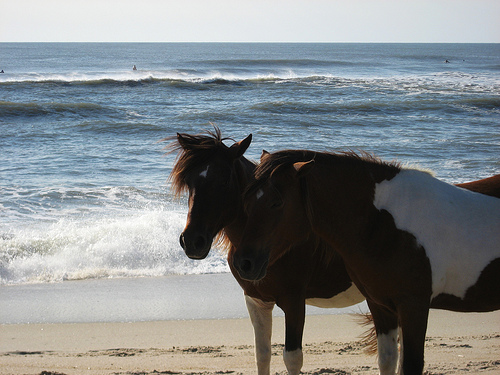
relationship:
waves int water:
[1, 66, 493, 93] [0, 37, 497, 295]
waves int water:
[0, 205, 232, 279] [0, 37, 497, 295]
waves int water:
[1, 98, 123, 118] [0, 37, 497, 295]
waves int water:
[266, 98, 498, 110] [0, 37, 497, 295]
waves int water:
[204, 57, 339, 65] [0, 37, 497, 295]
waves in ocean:
[0, 195, 208, 258] [0, 41, 498, 286]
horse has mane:
[120, 136, 487, 304] [158, 120, 262, 178]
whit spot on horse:
[403, 182, 459, 242] [237, 136, 495, 371]